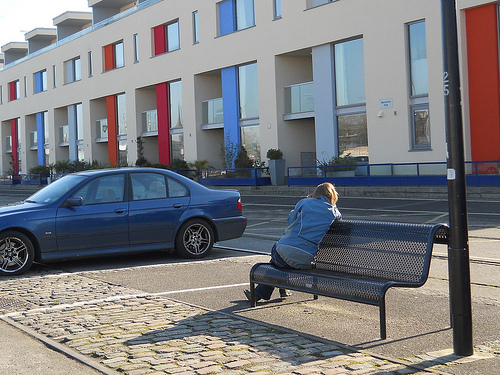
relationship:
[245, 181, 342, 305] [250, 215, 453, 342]
woman on bench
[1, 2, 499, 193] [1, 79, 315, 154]
building has balconies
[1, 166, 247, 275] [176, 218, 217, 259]
car has wheel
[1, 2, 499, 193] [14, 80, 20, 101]
building has window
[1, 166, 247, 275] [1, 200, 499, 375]
car in parking lot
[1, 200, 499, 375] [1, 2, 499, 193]
parking lot for building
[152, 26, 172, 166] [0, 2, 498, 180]
streak on wall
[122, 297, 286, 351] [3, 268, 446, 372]
shadow on ground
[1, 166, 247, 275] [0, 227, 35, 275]
car has wheel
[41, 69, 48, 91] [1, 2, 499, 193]
window on building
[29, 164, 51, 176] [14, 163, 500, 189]
shrubbery behind fence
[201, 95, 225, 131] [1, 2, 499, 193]
balcony on building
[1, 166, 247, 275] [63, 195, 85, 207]
car has mirror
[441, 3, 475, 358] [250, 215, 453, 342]
pole next to bench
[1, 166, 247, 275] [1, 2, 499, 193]
car near building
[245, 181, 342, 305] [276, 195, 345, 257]
woman wears jacket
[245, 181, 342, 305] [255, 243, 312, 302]
woman wears jeans